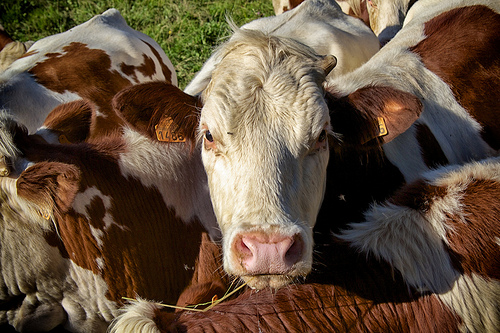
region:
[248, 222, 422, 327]
cow standing otuside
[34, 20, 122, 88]
cow standing otuside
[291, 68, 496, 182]
cow standing otuside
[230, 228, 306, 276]
pink nose of cow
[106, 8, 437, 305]
the head of a cow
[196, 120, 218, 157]
the eye of a cow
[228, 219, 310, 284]
the nose of a cow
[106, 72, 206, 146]
the ear of a cow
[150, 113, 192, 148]
a yellow tag on the cow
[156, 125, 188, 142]
black numbers on the tag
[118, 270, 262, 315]
hay in the cow's mouth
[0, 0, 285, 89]
green grass on the ground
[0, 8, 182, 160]
a brown and white cow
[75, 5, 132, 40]
the back of a cow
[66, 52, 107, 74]
the cow's skin is brown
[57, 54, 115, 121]
the cow's skin is brown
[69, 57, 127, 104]
the cow's skin is brown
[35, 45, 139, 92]
the cow's skin is brown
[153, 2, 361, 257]
the cow fur is white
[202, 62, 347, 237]
the cow fur is white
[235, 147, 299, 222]
the cow fur is white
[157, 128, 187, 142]
black writing on the tag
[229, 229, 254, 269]
the nostril of a cow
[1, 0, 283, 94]
a patch of green grass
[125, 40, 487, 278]
the cow is looking at the camera